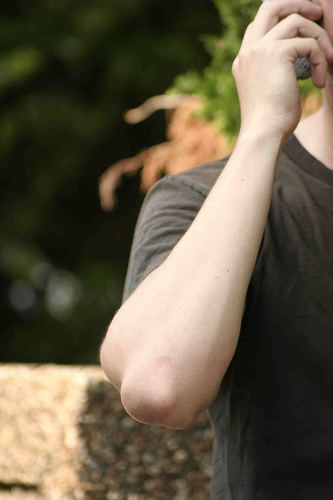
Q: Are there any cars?
A: No, there are no cars.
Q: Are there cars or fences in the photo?
A: No, there are no cars or fences.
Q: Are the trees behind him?
A: Yes, the trees are behind the man.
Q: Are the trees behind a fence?
A: No, the trees are behind the man.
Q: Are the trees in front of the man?
A: No, the trees are behind the man.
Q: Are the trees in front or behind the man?
A: The trees are behind the man.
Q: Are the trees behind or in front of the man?
A: The trees are behind the man.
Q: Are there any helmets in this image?
A: No, there are no helmets.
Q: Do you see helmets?
A: No, there are no helmets.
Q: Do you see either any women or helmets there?
A: No, there are no helmets or women.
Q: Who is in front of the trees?
A: The man is in front of the trees.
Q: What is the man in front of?
A: The man is in front of the trees.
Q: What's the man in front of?
A: The man is in front of the trees.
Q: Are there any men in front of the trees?
A: Yes, there is a man in front of the trees.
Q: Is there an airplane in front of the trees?
A: No, there is a man in front of the trees.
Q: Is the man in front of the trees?
A: Yes, the man is in front of the trees.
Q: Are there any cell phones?
A: Yes, there is a cell phone.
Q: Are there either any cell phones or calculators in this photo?
A: Yes, there is a cell phone.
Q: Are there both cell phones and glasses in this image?
A: No, there is a cell phone but no glasses.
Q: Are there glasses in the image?
A: No, there are no glasses.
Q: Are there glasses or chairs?
A: No, there are no glasses or chairs.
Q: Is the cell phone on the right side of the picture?
A: Yes, the cell phone is on the right of the image.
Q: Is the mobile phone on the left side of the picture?
A: No, the mobile phone is on the right of the image.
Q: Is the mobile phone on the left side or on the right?
A: The mobile phone is on the right of the image.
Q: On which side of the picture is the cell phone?
A: The cell phone is on the right of the image.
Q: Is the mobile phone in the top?
A: Yes, the mobile phone is in the top of the image.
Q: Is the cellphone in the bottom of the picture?
A: No, the cellphone is in the top of the image.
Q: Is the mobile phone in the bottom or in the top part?
A: The mobile phone is in the top of the image.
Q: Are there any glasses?
A: No, there are no glasses.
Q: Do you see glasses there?
A: No, there are no glasses.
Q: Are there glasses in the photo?
A: No, there are no glasses.